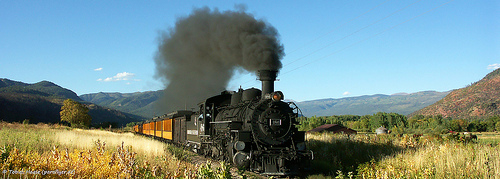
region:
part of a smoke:
[222, 30, 270, 92]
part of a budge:
[263, 106, 288, 129]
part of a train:
[255, 111, 281, 152]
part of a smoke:
[238, 33, 260, 73]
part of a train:
[261, 86, 302, 156]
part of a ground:
[397, 142, 402, 167]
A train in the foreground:
[130, 62, 326, 173]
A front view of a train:
[167, 72, 322, 173]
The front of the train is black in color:
[167, 68, 318, 175]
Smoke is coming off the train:
[135, 3, 295, 106]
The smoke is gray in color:
[150, 0, 291, 101]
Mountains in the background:
[3, 61, 453, 122]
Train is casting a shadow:
[289, 114, 420, 176]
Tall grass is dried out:
[353, 135, 496, 176]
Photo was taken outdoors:
[2, 2, 497, 177]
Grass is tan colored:
[396, 140, 498, 177]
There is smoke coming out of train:
[142, 10, 290, 80]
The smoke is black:
[149, 16, 327, 95]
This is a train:
[131, 102, 298, 163]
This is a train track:
[256, 170, 265, 176]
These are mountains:
[351, 52, 498, 140]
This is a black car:
[211, 115, 271, 158]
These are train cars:
[116, 109, 223, 161]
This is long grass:
[376, 145, 391, 151]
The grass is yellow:
[374, 146, 411, 158]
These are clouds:
[50, 55, 186, 119]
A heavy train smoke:
[218, 14, 285, 58]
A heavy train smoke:
[167, 47, 216, 98]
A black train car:
[202, 92, 315, 164]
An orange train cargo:
[151, 121, 177, 139]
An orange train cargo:
[140, 123, 150, 134]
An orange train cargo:
[131, 123, 139, 135]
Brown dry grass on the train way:
[56, 125, 152, 155]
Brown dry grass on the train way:
[385, 133, 451, 175]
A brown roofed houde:
[310, 120, 357, 136]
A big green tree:
[58, 101, 101, 130]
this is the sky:
[300, 2, 393, 57]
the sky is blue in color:
[311, 9, 381, 52]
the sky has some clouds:
[303, 65, 350, 93]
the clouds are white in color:
[302, 85, 330, 97]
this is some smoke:
[163, 28, 236, 90]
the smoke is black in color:
[179, 28, 231, 50]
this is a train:
[114, 79, 302, 164]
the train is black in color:
[246, 110, 271, 147]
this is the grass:
[360, 143, 460, 174]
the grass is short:
[401, 156, 463, 174]